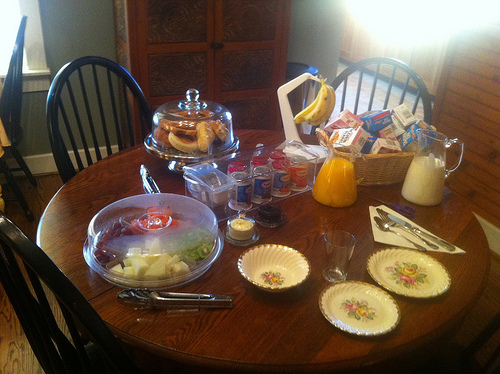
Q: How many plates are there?
A: Two.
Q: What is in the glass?
A: Nothing.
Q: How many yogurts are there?
A: 4.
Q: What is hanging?
A: Bananas.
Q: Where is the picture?
A: Kitchen.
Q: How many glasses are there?
A: 1.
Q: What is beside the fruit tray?
A: Tongs.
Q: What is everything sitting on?
A: Table.